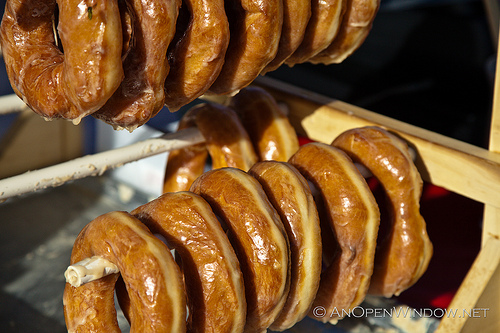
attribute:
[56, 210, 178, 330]
donuts — glazed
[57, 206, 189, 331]
donut — sticky, shiny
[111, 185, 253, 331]
donut — sticky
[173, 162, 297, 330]
donut — sticky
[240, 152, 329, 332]
donut — sticky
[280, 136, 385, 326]
donut — sticky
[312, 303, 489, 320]
letters — white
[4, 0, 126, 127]
donut — shiny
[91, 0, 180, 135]
donut — shiny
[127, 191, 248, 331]
donut — shiny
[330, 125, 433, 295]
donut — shiny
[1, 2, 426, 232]
donuts — brown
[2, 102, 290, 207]
rod — white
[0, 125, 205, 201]
stick — white glazed-covered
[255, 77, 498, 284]
box — wooden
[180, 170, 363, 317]
donuts — glazed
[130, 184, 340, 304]
donut — brown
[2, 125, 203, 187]
dowel — white